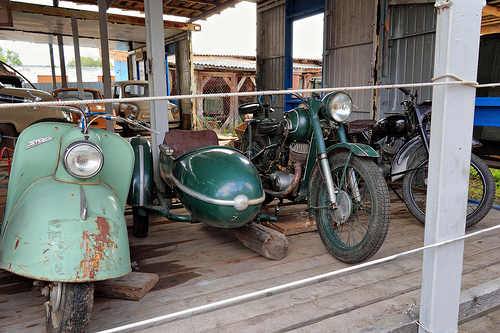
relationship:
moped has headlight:
[3, 109, 164, 332] [64, 140, 107, 181]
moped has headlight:
[229, 89, 393, 266] [327, 88, 355, 126]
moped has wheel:
[3, 109, 164, 332] [41, 279, 99, 332]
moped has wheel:
[229, 89, 393, 266] [306, 151, 392, 266]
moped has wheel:
[348, 91, 499, 230] [403, 145, 495, 226]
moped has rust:
[3, 109, 164, 332] [75, 215, 116, 279]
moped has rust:
[3, 109, 164, 332] [12, 238, 23, 251]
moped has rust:
[3, 109, 164, 332] [8, 262, 11, 271]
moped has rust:
[229, 89, 393, 266] [287, 171, 301, 193]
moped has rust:
[229, 89, 393, 266] [359, 153, 371, 159]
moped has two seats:
[229, 89, 393, 266] [161, 123, 291, 161]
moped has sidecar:
[229, 89, 393, 266] [131, 126, 273, 237]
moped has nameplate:
[3, 109, 164, 332] [27, 135, 55, 153]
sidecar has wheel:
[131, 126, 273, 237] [132, 137, 153, 239]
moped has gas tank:
[229, 89, 393, 266] [268, 171, 294, 191]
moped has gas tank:
[348, 91, 499, 230] [377, 161, 391, 179]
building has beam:
[327, 2, 437, 123] [340, 49, 347, 89]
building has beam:
[327, 2, 437, 123] [351, 46, 359, 89]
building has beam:
[327, 2, 437, 123] [336, 3, 343, 46]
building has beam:
[327, 2, 437, 123] [360, 4, 367, 40]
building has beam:
[327, 2, 437, 123] [323, 52, 332, 87]